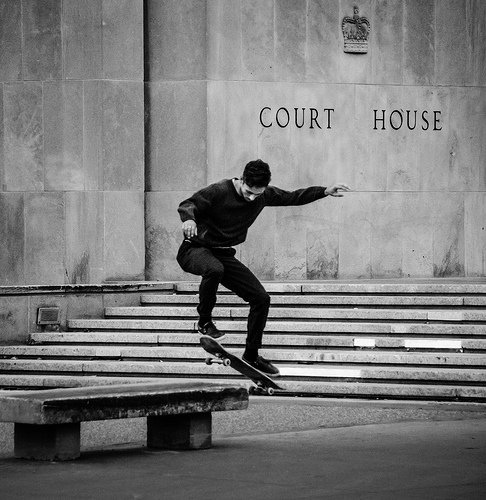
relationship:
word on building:
[259, 105, 335, 133] [1, 1, 484, 343]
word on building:
[372, 107, 444, 133] [1, 1, 484, 343]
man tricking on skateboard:
[176, 157, 356, 377] [199, 336, 287, 395]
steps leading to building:
[1, 280, 486, 403] [1, 1, 484, 343]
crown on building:
[339, 5, 372, 55] [1, 1, 484, 343]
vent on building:
[36, 306, 61, 327] [1, 1, 484, 343]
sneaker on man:
[195, 321, 223, 339] [176, 157, 356, 377]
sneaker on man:
[242, 351, 280, 381] [176, 157, 356, 377]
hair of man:
[245, 159, 272, 187] [176, 157, 356, 377]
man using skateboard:
[176, 157, 356, 377] [199, 336, 287, 395]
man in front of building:
[176, 157, 356, 377] [1, 1, 484, 343]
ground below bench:
[1, 394, 482, 500] [2, 377, 252, 464]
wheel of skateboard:
[224, 355, 234, 367] [199, 336, 287, 395]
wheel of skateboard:
[204, 355, 216, 369] [199, 336, 287, 395]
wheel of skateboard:
[265, 386, 279, 397] [199, 336, 287, 395]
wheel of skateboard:
[248, 385, 257, 397] [199, 336, 287, 395]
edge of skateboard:
[214, 342, 281, 387] [199, 336, 287, 395]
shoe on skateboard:
[242, 351, 280, 381] [199, 336, 287, 395]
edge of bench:
[1, 397, 45, 423] [2, 377, 252, 464]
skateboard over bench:
[199, 336, 287, 395] [2, 377, 252, 464]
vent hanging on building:
[36, 306, 61, 327] [1, 1, 484, 343]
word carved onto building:
[259, 105, 335, 133] [1, 1, 484, 343]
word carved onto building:
[372, 107, 444, 133] [1, 1, 484, 343]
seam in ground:
[83, 414, 485, 451] [1, 394, 482, 500]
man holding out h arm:
[176, 157, 356, 377] [269, 182, 356, 208]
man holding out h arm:
[176, 157, 356, 377] [176, 183, 220, 239]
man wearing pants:
[176, 157, 356, 377] [176, 239, 271, 359]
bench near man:
[2, 377, 252, 464] [176, 157, 356, 377]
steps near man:
[1, 280, 486, 403] [176, 157, 356, 377]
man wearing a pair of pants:
[176, 157, 356, 377] [176, 239, 271, 359]